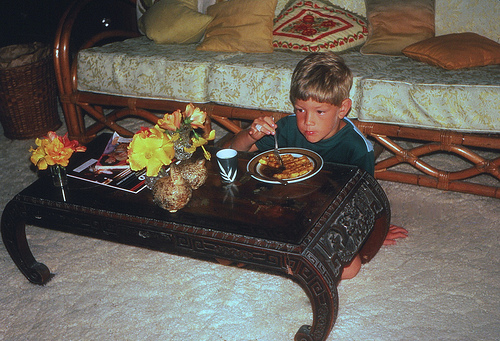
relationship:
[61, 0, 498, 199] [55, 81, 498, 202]
couch on wooden base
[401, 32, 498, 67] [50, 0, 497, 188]
pillows on sofa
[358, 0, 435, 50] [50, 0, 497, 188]
pillows on sofa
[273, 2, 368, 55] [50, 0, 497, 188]
pillows on sofa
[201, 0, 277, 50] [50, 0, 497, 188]
pillows on sofa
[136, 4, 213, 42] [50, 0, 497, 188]
pillows on sofa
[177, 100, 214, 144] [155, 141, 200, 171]
flower in vase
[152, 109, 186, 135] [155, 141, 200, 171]
flower in vase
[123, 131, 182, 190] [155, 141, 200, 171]
flower in vase